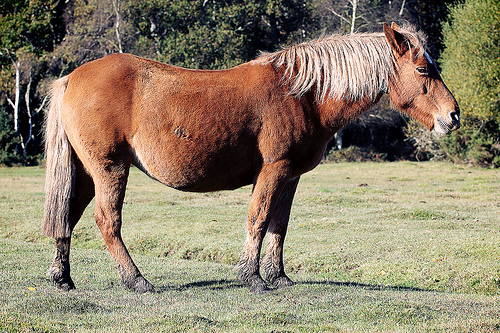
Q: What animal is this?
A: A horse.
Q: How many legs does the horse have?
A: 4.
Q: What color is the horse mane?
A: Blonde.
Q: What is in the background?
A: Trees.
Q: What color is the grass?
A: Green.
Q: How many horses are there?
A: 1.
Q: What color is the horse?
A: Brown.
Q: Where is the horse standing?
A: In the grass.